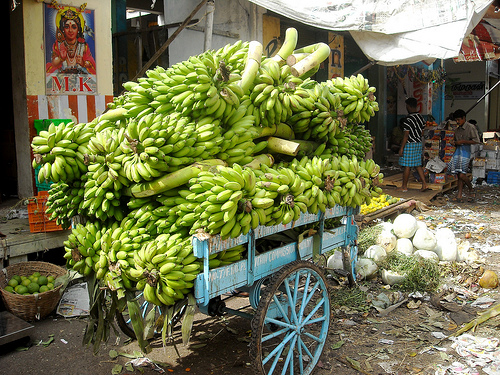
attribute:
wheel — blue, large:
[248, 261, 333, 374]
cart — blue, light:
[115, 196, 361, 374]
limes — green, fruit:
[7, 272, 57, 292]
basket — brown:
[3, 259, 69, 319]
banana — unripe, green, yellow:
[51, 146, 67, 154]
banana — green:
[222, 201, 236, 210]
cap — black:
[403, 97, 417, 108]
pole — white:
[202, 2, 214, 52]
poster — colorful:
[43, 2, 98, 95]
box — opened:
[482, 130, 499, 145]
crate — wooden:
[429, 171, 448, 184]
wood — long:
[361, 199, 417, 225]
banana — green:
[258, 74, 275, 86]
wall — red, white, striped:
[28, 94, 116, 195]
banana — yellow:
[161, 262, 176, 273]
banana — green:
[195, 73, 212, 83]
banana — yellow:
[356, 74, 364, 91]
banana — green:
[146, 78, 159, 83]